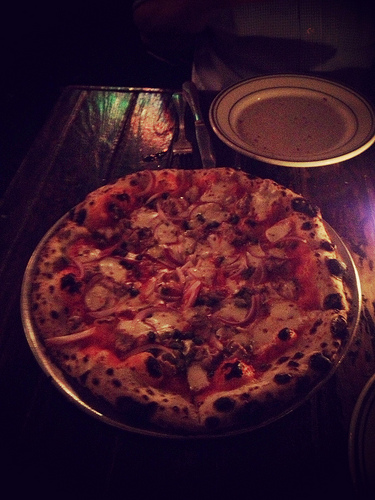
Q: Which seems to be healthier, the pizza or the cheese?
A: The cheese is healthier than the pizza.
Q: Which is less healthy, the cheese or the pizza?
A: The pizza is less healthy than the cheese.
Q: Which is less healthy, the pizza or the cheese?
A: The pizza is less healthy than the cheese.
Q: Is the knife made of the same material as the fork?
A: Yes, both the knife and the fork are made of metal.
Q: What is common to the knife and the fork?
A: The material, both the knife and the fork are metallic.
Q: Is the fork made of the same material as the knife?
A: Yes, both the fork and the knife are made of metal.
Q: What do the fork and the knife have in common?
A: The material, both the fork and the knife are metallic.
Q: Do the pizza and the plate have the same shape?
A: Yes, both the pizza and the plate are round.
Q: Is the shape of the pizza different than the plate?
A: No, both the pizza and the plate are round.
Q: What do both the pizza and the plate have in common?
A: The shape, both the pizza and the plate are round.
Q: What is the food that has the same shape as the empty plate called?
A: The food is a pizza.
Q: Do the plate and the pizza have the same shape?
A: Yes, both the plate and the pizza are round.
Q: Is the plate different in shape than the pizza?
A: No, both the plate and the pizza are round.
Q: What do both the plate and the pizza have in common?
A: The shape, both the plate and the pizza are round.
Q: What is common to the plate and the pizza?
A: The shape, both the plate and the pizza are round.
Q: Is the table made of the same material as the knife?
A: No, the table is made of wood and the knife is made of metal.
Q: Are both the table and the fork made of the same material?
A: No, the table is made of wood and the fork is made of metal.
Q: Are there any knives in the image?
A: Yes, there is a knife.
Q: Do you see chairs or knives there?
A: Yes, there is a knife.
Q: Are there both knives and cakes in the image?
A: No, there is a knife but no cakes.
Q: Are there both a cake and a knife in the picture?
A: No, there is a knife but no cakes.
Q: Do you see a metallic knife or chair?
A: Yes, there is a metal knife.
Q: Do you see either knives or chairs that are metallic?
A: Yes, the knife is metallic.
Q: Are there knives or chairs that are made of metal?
A: Yes, the knife is made of metal.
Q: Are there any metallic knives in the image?
A: Yes, there is a metal knife.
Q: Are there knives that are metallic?
A: Yes, there is a knife that is metallic.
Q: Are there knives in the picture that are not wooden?
A: Yes, there is a metallic knife.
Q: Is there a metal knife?
A: Yes, there is a knife that is made of metal.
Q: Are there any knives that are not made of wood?
A: Yes, there is a knife that is made of metal.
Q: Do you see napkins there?
A: No, there are no napkins.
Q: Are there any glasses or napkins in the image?
A: No, there are no napkins or glasses.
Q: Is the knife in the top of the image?
A: Yes, the knife is in the top of the image.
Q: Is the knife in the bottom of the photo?
A: No, the knife is in the top of the image.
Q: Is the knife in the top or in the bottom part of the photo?
A: The knife is in the top of the image.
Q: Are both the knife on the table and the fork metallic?
A: Yes, both the knife and the fork are metallic.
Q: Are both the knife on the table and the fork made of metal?
A: Yes, both the knife and the fork are made of metal.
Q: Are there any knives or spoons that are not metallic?
A: No, there is a knife but it is metallic.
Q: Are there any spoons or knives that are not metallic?
A: No, there is a knife but it is metallic.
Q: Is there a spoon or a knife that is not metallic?
A: No, there is a knife but it is metallic.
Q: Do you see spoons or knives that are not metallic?
A: No, there is a knife but it is metallic.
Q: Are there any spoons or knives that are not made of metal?
A: No, there is a knife but it is made of metal.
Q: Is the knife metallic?
A: Yes, the knife is metallic.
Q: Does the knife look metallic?
A: Yes, the knife is metallic.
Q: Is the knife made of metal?
A: Yes, the knife is made of metal.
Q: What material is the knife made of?
A: The knife is made of metal.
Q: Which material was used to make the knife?
A: The knife is made of metal.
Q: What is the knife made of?
A: The knife is made of metal.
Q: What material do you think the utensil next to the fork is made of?
A: The knife is made of metal.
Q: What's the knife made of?
A: The knife is made of metal.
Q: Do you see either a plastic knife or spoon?
A: No, there is a knife but it is metallic.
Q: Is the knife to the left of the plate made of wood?
A: No, the knife is made of metal.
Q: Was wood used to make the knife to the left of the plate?
A: No, the knife is made of metal.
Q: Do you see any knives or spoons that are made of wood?
A: No, there is a knife but it is made of metal.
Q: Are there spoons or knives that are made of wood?
A: No, there is a knife but it is made of metal.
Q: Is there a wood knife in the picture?
A: No, there is a knife but it is made of metal.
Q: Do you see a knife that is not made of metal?
A: No, there is a knife but it is made of metal.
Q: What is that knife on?
A: The knife is on the table.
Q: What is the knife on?
A: The knife is on the table.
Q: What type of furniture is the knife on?
A: The knife is on the table.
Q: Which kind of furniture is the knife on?
A: The knife is on the table.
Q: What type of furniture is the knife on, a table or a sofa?
A: The knife is on a table.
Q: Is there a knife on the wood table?
A: Yes, there is a knife on the table.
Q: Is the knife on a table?
A: Yes, the knife is on a table.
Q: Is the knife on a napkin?
A: No, the knife is on a table.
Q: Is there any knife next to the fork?
A: Yes, there is a knife next to the fork.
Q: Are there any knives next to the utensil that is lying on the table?
A: Yes, there is a knife next to the fork.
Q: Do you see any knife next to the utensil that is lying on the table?
A: Yes, there is a knife next to the fork.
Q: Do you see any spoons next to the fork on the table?
A: No, there is a knife next to the fork.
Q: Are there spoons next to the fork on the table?
A: No, there is a knife next to the fork.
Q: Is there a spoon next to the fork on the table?
A: No, there is a knife next to the fork.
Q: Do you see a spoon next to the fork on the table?
A: No, there is a knife next to the fork.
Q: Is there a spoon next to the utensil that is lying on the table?
A: No, there is a knife next to the fork.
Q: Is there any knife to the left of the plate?
A: Yes, there is a knife to the left of the plate.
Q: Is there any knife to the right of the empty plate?
A: No, the knife is to the left of the plate.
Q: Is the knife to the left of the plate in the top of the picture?
A: Yes, the knife is to the left of the plate.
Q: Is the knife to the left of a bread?
A: No, the knife is to the left of the plate.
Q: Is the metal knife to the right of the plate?
A: No, the knife is to the left of the plate.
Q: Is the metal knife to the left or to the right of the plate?
A: The knife is to the left of the plate.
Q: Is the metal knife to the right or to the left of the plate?
A: The knife is to the left of the plate.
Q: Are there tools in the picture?
A: No, there are no tools.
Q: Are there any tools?
A: No, there are no tools.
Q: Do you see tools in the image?
A: No, there are no tools.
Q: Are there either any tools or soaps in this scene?
A: No, there are no tools or soaps.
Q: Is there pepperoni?
A: No, there is no pepperoni.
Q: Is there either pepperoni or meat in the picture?
A: No, there are no pepperoni or meat.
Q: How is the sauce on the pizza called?
A: The sauce is tomato sauce.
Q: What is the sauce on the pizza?
A: The sauce is tomato sauce.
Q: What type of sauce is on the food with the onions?
A: The sauce is tomato sauce.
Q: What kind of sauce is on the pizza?
A: The sauce is tomato sauce.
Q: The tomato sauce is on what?
A: The tomato sauce is on the pizza.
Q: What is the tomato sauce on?
A: The tomato sauce is on the pizza.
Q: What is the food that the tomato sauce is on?
A: The food is a pizza.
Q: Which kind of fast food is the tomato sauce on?
A: The tomato sauce is on the pizza.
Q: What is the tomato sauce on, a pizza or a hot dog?
A: The tomato sauce is on a pizza.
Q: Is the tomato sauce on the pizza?
A: Yes, the tomato sauce is on the pizza.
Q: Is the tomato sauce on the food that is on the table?
A: Yes, the tomato sauce is on the pizza.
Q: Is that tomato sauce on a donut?
A: No, the tomato sauce is on the pizza.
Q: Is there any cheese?
A: Yes, there is cheese.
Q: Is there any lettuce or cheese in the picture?
A: Yes, there is cheese.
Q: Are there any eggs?
A: No, there are no eggs.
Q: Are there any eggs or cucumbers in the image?
A: No, there are no eggs or cucumbers.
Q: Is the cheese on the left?
A: Yes, the cheese is on the left of the image.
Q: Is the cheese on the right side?
A: No, the cheese is on the left of the image.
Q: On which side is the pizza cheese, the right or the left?
A: The cheese is on the left of the image.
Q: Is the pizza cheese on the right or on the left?
A: The cheese is on the left of the image.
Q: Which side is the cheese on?
A: The cheese is on the left of the image.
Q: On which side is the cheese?
A: The cheese is on the left of the image.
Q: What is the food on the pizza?
A: The food is cheese.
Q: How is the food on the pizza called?
A: The food is cheese.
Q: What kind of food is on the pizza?
A: The food is cheese.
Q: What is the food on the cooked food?
A: The food is cheese.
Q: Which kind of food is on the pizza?
A: The food is cheese.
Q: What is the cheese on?
A: The cheese is on the pizza.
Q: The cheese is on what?
A: The cheese is on the pizza.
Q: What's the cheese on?
A: The cheese is on the pizza.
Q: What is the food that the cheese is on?
A: The food is a pizza.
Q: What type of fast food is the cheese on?
A: The cheese is on the pizza.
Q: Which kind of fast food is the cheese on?
A: The cheese is on the pizza.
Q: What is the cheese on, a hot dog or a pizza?
A: The cheese is on a pizza.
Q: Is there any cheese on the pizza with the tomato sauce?
A: Yes, there is cheese on the pizza.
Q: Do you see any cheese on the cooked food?
A: Yes, there is cheese on the pizza.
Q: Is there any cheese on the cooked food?
A: Yes, there is cheese on the pizza.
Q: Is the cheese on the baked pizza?
A: Yes, the cheese is on the pizza.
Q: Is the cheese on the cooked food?
A: Yes, the cheese is on the pizza.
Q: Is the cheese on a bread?
A: No, the cheese is on the pizza.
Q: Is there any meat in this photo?
A: No, there is no meat.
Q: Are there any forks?
A: Yes, there is a fork.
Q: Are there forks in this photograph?
A: Yes, there is a fork.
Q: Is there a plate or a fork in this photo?
A: Yes, there is a fork.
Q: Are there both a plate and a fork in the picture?
A: Yes, there are both a fork and a plate.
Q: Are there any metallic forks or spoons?
A: Yes, there is a metal fork.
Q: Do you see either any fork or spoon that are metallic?
A: Yes, the fork is metallic.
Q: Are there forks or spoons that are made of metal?
A: Yes, the fork is made of metal.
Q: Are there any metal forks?
A: Yes, there is a fork that is made of metal.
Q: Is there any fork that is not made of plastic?
A: Yes, there is a fork that is made of metal.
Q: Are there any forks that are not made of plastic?
A: Yes, there is a fork that is made of metal.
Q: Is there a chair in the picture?
A: No, there are no chairs.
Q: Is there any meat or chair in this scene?
A: No, there are no chairs or meat.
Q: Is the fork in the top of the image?
A: Yes, the fork is in the top of the image.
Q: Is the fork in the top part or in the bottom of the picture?
A: The fork is in the top of the image.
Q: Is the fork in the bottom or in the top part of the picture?
A: The fork is in the top of the image.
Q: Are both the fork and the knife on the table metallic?
A: Yes, both the fork and the knife are metallic.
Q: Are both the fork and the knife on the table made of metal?
A: Yes, both the fork and the knife are made of metal.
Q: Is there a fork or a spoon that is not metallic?
A: No, there is a fork but it is metallic.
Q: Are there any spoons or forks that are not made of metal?
A: No, there is a fork but it is made of metal.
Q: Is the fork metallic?
A: Yes, the fork is metallic.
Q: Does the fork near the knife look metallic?
A: Yes, the fork is metallic.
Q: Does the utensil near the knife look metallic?
A: Yes, the fork is metallic.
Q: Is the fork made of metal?
A: Yes, the fork is made of metal.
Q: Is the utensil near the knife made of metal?
A: Yes, the fork is made of metal.